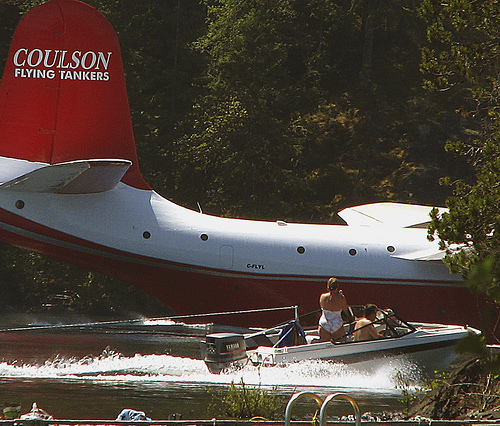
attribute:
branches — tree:
[432, 142, 497, 309]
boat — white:
[208, 303, 482, 377]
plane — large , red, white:
[152, 191, 454, 316]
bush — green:
[200, 369, 295, 424]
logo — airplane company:
[2, 33, 120, 91]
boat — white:
[202, 289, 483, 389]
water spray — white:
[277, 358, 414, 392]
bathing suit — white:
[318, 307, 343, 332]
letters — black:
[242, 259, 269, 272]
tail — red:
[7, 7, 161, 199]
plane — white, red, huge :
[9, 18, 498, 339]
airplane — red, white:
[0, 0, 495, 333]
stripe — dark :
[310, 320, 482, 382]